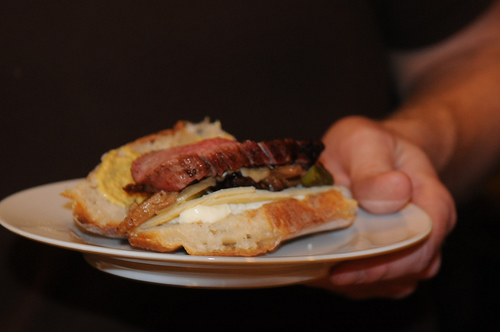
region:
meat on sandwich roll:
[125, 115, 331, 202]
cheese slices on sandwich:
[147, 187, 328, 229]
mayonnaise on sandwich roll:
[138, 189, 383, 281]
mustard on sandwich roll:
[84, 134, 146, 214]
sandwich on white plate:
[71, 126, 420, 298]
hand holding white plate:
[179, 99, 495, 301]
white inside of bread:
[110, 179, 359, 251]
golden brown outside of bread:
[212, 182, 370, 256]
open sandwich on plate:
[99, 126, 431, 293]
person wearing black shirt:
[109, 0, 494, 178]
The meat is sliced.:
[125, 128, 325, 183]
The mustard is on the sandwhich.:
[89, 133, 124, 201]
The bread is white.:
[93, 140, 343, 267]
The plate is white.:
[7, 112, 429, 316]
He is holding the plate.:
[325, 98, 439, 328]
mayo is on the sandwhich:
[168, 185, 288, 240]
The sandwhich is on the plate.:
[45, 105, 350, 283]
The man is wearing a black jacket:
[47, 15, 475, 152]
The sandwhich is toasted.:
[89, 112, 362, 288]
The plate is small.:
[0, 119, 467, 303]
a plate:
[54, 71, 354, 329]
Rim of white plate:
[59, 237, 114, 257]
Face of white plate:
[303, 239, 338, 255]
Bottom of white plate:
[131, 269, 236, 284]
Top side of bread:
[219, 220, 281, 252]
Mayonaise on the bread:
[181, 209, 228, 221]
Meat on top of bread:
[158, 148, 203, 177]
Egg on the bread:
[96, 162, 124, 194]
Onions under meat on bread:
[185, 184, 207, 193]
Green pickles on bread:
[308, 168, 325, 184]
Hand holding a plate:
[315, 122, 460, 286]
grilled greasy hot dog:
[124, 118, 341, 193]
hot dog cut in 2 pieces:
[133, 137, 326, 192]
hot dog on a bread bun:
[64, 134, 366, 261]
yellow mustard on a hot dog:
[94, 136, 189, 213]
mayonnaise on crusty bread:
[177, 183, 330, 262]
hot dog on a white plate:
[6, 127, 379, 279]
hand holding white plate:
[316, 99, 459, 296]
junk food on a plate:
[59, 107, 412, 280]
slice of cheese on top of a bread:
[141, 174, 326, 231]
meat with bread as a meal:
[126, 127, 367, 267]